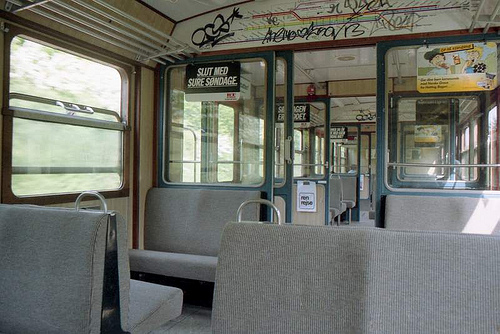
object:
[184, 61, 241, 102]
sign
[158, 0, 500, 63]
wall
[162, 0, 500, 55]
wall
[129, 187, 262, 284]
bench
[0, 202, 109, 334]
bench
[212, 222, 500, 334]
bench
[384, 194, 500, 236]
bench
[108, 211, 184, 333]
bench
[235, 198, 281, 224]
handhold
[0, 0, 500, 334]
bus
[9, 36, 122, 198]
window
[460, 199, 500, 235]
light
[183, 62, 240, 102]
paper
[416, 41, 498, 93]
advert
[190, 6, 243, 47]
graffiti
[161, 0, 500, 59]
wall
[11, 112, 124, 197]
window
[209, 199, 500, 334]
seat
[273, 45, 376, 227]
inside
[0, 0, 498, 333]
train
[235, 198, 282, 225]
handle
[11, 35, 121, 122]
sky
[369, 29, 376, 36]
tagging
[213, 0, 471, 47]
map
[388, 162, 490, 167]
pipe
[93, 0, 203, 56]
rack